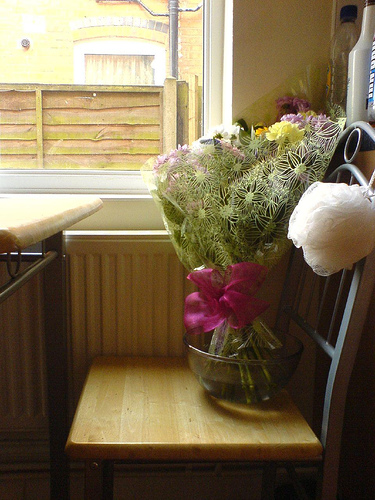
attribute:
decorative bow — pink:
[180, 260, 273, 337]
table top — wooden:
[2, 177, 113, 253]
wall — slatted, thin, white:
[1, 82, 163, 172]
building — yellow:
[3, 14, 214, 177]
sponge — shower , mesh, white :
[283, 174, 373, 278]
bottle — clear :
[330, 7, 356, 120]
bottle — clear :
[347, 0, 370, 123]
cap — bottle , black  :
[337, 3, 361, 22]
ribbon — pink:
[182, 261, 275, 333]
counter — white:
[8, 188, 103, 249]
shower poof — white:
[286, 169, 373, 276]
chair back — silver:
[273, 120, 374, 465]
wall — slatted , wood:
[1, 73, 203, 169]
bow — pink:
[180, 268, 259, 327]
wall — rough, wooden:
[0, 0, 205, 87]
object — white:
[275, 174, 372, 276]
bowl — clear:
[189, 325, 302, 411]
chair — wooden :
[65, 121, 374, 498]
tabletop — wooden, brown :
[0, 195, 103, 245]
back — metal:
[323, 124, 362, 428]